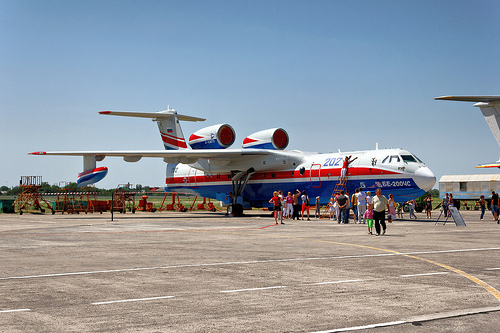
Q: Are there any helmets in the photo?
A: No, there are no helmets.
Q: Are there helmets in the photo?
A: No, there are no helmets.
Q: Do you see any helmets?
A: No, there are no helmets.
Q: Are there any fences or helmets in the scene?
A: No, there are no helmets or fences.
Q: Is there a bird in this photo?
A: No, there are no birds.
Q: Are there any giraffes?
A: No, there are no giraffes.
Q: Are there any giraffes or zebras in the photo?
A: No, there are no giraffes or zebras.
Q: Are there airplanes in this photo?
A: Yes, there is an airplane.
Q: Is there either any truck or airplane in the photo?
A: Yes, there is an airplane.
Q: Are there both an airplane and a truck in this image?
A: No, there is an airplane but no trucks.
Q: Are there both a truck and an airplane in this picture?
A: No, there is an airplane but no trucks.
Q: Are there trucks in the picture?
A: No, there are no trucks.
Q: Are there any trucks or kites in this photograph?
A: No, there are no trucks or kites.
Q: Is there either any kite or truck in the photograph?
A: No, there are no trucks or kites.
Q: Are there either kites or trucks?
A: No, there are no trucks or kites.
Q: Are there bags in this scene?
A: No, there are no bags.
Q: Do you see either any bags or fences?
A: No, there are no bags or fences.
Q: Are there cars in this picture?
A: No, there are no cars.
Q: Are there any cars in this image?
A: No, there are no cars.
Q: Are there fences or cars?
A: No, there are no cars or fences.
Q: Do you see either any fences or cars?
A: No, there are no cars or fences.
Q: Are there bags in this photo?
A: No, there are no bags.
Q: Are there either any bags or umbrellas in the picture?
A: No, there are no bags or umbrellas.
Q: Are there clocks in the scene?
A: No, there are no clocks.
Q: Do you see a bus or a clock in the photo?
A: No, there are no clocks or buses.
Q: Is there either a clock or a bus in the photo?
A: No, there are no clocks or buses.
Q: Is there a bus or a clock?
A: No, there are no clocks or buses.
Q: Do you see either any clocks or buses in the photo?
A: No, there are no clocks or buses.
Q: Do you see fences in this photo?
A: No, there are no fences.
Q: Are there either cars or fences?
A: No, there are no fences or cars.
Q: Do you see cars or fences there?
A: No, there are no fences or cars.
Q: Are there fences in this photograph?
A: No, there are no fences.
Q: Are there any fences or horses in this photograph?
A: No, there are no fences or horses.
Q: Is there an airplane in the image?
A: Yes, there is an airplane.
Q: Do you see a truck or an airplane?
A: Yes, there is an airplane.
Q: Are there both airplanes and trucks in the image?
A: No, there is an airplane but no trucks.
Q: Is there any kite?
A: No, there are no kites.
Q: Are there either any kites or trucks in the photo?
A: No, there are no kites or trucks.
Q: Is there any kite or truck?
A: No, there are no kites or trucks.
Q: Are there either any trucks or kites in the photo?
A: No, there are no kites or trucks.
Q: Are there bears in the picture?
A: No, there are no bears.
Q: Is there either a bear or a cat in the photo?
A: No, there are no bears or cats.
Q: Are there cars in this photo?
A: No, there are no cars.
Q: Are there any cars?
A: No, there are no cars.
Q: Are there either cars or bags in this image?
A: No, there are no cars or bags.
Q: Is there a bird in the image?
A: No, there are no birds.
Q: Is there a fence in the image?
A: No, there are no fences.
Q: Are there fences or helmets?
A: No, there are no fences or helmets.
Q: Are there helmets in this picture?
A: No, there are no helmets.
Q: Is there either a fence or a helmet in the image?
A: No, there are no helmets or fences.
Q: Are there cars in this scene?
A: No, there are no cars.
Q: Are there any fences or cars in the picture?
A: No, there are no cars or fences.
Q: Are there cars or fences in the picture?
A: No, there are no cars or fences.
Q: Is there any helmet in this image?
A: No, there are no helmets.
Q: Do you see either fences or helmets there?
A: No, there are no helmets or fences.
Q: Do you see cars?
A: No, there are no cars.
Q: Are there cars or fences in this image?
A: No, there are no cars or fences.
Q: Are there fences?
A: No, there are no fences.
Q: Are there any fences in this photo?
A: No, there are no fences.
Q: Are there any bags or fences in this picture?
A: No, there are no fences or bags.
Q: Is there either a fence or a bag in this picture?
A: No, there are no fences or bags.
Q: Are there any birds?
A: No, there are no birds.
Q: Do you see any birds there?
A: No, there are no birds.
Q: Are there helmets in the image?
A: No, there are no helmets.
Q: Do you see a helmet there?
A: No, there are no helmets.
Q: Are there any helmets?
A: No, there are no helmets.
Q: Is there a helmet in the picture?
A: No, there are no helmets.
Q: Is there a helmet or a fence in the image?
A: No, there are no helmets or fences.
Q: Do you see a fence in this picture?
A: No, there are no fences.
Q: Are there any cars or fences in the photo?
A: No, there are no fences or cars.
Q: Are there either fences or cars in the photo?
A: No, there are no fences or cars.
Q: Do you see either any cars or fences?
A: No, there are no fences or cars.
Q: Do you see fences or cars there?
A: No, there are no fences or cars.